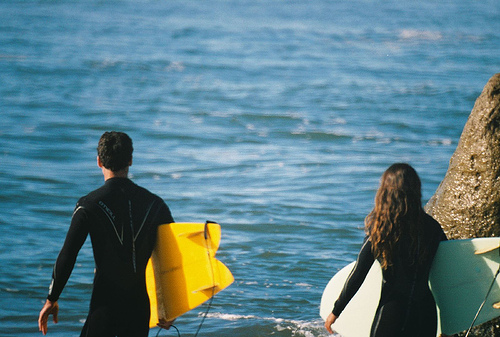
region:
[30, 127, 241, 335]
man carrying orange surfboard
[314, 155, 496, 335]
woman carrying white surfboard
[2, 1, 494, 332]
dark blue ocean water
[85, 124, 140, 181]
head of short dark hair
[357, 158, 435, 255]
long wavy dark brown hair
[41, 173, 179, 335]
black and white wet suit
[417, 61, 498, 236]
large boulder next to woman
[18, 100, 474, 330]
two people preparing to surf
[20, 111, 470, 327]
a man and lady carrying surfboards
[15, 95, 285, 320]
a man carrying a yellow surfboard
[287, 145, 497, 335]
a woman carrying a white surfboard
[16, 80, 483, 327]
a young couple preparing to go surfing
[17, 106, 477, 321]
a couple of people ready to surf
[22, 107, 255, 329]
A man carrying a surfboard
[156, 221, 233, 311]
The yellow surfboard the guy is carrying.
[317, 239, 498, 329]
The white surfboard the girl is carrying.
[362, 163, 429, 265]
The hair of the girl.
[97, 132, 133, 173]
The short hair of the guy.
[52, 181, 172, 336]
The wet suit the guy is wearing.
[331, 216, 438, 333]
The wet suit the girl is wearing.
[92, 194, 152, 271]
The design on the back of the guy's wet suit.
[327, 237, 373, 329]
The girl's left arm.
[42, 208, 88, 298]
The guy's left arm.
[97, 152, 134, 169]
The back of the guy's ears.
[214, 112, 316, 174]
blue color in the ocean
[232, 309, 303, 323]
small waves in the ocean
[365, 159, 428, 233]
long curly black hair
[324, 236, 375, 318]
long black shiny wet suit arm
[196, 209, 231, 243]
black strings on surf board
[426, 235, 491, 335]
white surf board under woman's arm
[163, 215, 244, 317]
yellow color on surf board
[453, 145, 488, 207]
tall brown rock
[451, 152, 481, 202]
deep holes in the brown rock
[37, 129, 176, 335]
man in a wet suit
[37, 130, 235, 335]
man with a surf board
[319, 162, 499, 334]
woman with a surf board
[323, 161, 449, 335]
woman in a wetsuit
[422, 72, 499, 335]
rock near the water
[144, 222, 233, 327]
yellow surf board with a strap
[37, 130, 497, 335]
man and woman about to surf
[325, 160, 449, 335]
girl with long hair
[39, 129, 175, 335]
boy with short hair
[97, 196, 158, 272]
graphic on a wet suit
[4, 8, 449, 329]
a body of water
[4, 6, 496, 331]
a body of blue water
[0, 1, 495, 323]
a body of water that is blue